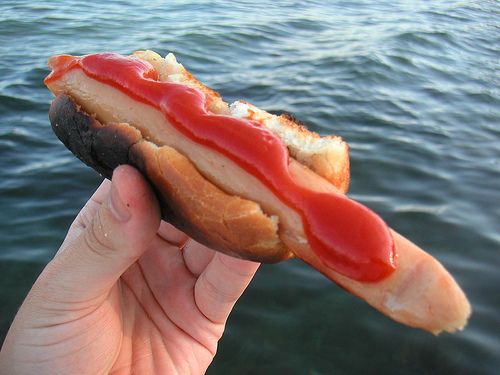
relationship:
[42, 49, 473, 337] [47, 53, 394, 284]
footlong with ketchup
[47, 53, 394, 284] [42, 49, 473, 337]
ketchup on footlong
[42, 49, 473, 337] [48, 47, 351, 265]
footlong on a bun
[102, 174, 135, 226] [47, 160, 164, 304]
nail on thumb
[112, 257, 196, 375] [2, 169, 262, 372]
palm of hand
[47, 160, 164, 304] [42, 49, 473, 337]
thumb holding footlong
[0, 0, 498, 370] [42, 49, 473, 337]
water behind footlong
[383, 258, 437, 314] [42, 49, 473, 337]
mark on footlong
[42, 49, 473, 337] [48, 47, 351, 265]
footlong in bun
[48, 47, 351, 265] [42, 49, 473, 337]
bun holding footlong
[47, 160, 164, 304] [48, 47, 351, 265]
thumb supports bun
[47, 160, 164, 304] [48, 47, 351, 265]
thumb holding bun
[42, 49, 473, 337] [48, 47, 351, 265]
footlong to big for bun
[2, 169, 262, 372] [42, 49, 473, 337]
hand holding footlong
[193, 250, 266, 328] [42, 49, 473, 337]
pinky holding footlong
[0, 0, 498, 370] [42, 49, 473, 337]
water below footlong